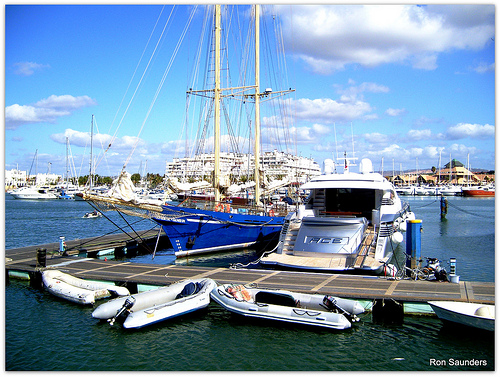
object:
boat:
[207, 281, 369, 331]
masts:
[184, 4, 256, 212]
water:
[3, 195, 495, 371]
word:
[302, 235, 345, 247]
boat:
[259, 171, 419, 276]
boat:
[423, 301, 494, 331]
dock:
[4, 227, 495, 306]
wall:
[164, 156, 212, 182]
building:
[163, 148, 324, 183]